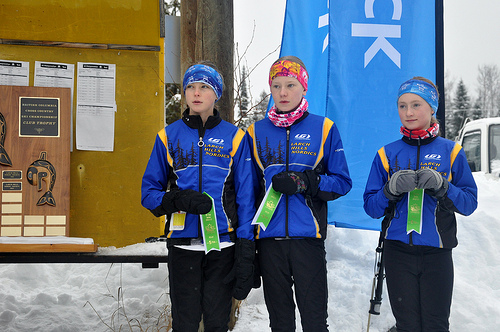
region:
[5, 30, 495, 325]
The girls are in the snow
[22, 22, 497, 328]
The girls are part of a ski team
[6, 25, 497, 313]
The girls are in a mountain area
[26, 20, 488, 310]
The girls have just won an award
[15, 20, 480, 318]
The girls are all good friends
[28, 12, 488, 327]
The girls go to the same school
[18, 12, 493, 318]
The girls enjoy the same sport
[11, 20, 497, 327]
The girls are all wearing headbands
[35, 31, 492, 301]
The girls are all wearing jackets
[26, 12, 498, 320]
The girls are all wearing dark pants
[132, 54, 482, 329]
a group of young skiers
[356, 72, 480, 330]
a young skier holding a green ribbon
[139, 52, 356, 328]
two young skiers holding green ribbons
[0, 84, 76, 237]
a commemorative plaque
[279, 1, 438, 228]
a blue banner with text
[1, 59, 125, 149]
many postings on a wall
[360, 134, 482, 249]
a blue ski jacket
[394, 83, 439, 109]
a blue bandanna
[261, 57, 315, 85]
an orange bandanna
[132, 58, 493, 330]
three girls out skiing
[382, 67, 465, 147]
girl wearing blue headband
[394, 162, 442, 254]
girl holding green ribbon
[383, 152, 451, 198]
girl wearing grey gloves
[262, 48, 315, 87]
girl wearing pink headband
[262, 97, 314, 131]
girl wearing pink scarf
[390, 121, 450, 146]
girl wearing red scarf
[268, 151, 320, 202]
girl wearing blue gloves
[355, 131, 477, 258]
girl wearing blue jacket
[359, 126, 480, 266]
jacket has yellow trim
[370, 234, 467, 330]
girl wearing blue pants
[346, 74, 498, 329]
Girl wearing a blue jacket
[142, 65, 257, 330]
Girl wearing black pants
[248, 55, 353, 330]
Girl wearing a blue jacket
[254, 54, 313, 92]
Pink headband on girl's head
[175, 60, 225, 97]
Blue headband on girl's head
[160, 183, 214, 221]
Black mitten on girl's hand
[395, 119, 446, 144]
Red scarf around girl's neck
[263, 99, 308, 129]
Pink scarf around girl's neck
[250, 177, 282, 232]
Ribbon in girl's hand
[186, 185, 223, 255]
ribbon in girl's hand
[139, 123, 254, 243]
a black white blue and yellow winter jacket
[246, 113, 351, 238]
a black white blue and yellow winter jacket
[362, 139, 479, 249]
a black white blue and yellow winter jacket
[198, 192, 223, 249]
a gold green and white award ribbon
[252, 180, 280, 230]
a gold green and white award ribbon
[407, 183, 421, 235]
a gold green and white award ribbon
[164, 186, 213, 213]
a black winter mitten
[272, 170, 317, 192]
a black winter mitten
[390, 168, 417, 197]
a grey winter glove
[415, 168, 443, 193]
a grey winter glove